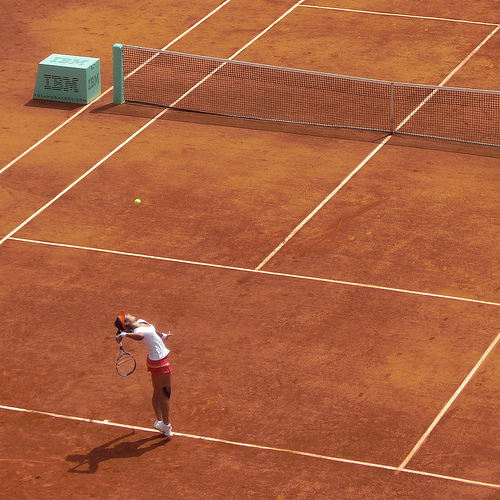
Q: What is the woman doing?
A: Hitting a tennis ball.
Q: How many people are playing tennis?
A: One.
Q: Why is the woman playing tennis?
A: For fun.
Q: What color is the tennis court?
A: Brown.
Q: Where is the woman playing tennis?
A: On the tennis court.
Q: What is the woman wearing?
A: A shirt and a tennis skirt.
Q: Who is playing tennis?
A: The woman.